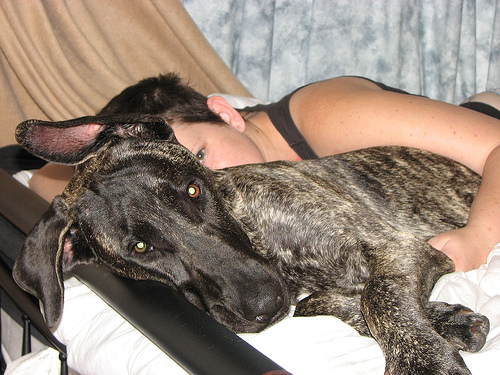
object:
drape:
[0, 0, 255, 146]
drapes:
[178, 0, 500, 105]